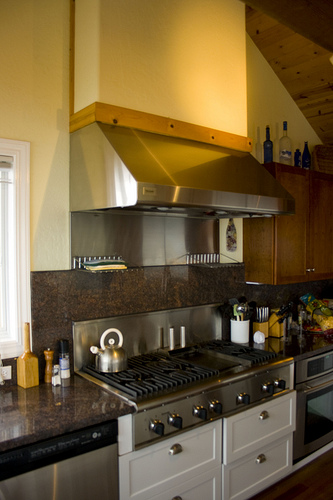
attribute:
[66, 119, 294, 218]
hood cover — silver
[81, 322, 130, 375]
kettle — silver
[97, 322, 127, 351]
handle — white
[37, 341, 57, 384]
grinder — brown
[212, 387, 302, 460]
drawer — white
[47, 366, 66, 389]
shaker — white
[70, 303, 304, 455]
cooktop — large, stainless steel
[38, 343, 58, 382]
pepper mill — wooden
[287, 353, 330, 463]
oven — stainles steel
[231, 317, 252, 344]
crock — white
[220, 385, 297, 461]
kitchen drawer — white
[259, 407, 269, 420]
handle — stainless steel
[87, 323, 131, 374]
tea kettle — stainless steel, silver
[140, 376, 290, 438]
knobs — black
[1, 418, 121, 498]
dishwasher — black, Silver, stainles steel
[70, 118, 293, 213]
range hood — brush metal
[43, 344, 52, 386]
grinder — wooden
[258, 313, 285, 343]
knife block — wooden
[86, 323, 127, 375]
kettle — silver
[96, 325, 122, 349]
handle — white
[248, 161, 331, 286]
cabinets — wooden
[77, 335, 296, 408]
stove top — gas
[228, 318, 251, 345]
jar — white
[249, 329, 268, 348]
timer — white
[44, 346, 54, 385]
pepper grinder — brown, wooden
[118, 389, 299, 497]
drawers — white, wooden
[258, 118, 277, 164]
bottle — blue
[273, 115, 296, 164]
bottle — clear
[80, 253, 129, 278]
holders — green, yellow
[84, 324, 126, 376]
kettle — stainless steel, white, metal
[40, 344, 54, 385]
shaker — wooden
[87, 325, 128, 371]
tea kettle — silver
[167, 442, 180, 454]
handle — chrome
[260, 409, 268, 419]
handle — chrome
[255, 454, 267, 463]
handle — chrome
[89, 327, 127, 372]
tea kettle — brushed metal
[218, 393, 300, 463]
drawer — white, wooden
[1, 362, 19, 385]
outlet — electric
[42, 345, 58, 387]
pepper mill — small, wooden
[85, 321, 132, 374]
kettle — stainless steel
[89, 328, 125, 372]
kettle — silver